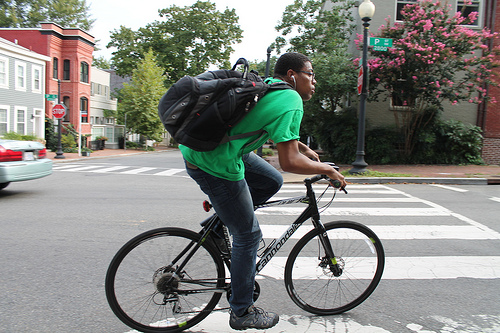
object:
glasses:
[293, 69, 317, 81]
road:
[0, 146, 500, 333]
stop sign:
[52, 104, 67, 119]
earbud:
[286, 68, 296, 81]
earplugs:
[291, 74, 298, 90]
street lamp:
[350, 0, 377, 175]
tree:
[115, 46, 175, 150]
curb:
[49, 148, 169, 164]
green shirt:
[175, 76, 308, 181]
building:
[1, 23, 95, 155]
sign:
[367, 37, 393, 52]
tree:
[369, 3, 489, 160]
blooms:
[388, 59, 395, 65]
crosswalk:
[209, 171, 499, 333]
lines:
[236, 254, 500, 281]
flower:
[452, 11, 463, 20]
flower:
[466, 10, 481, 24]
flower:
[376, 24, 385, 31]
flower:
[416, 11, 428, 26]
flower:
[405, 41, 414, 49]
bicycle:
[103, 151, 390, 332]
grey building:
[0, 36, 50, 148]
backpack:
[156, 58, 294, 152]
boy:
[179, 49, 346, 330]